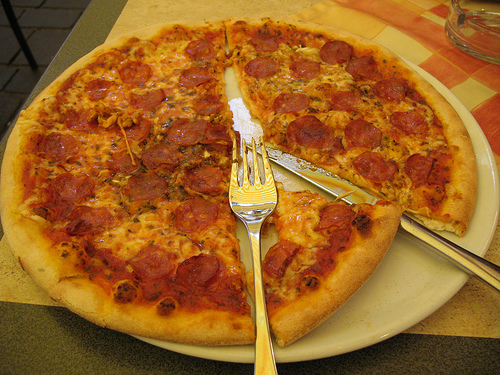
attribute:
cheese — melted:
[111, 187, 208, 271]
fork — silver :
[218, 134, 285, 374]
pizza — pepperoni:
[1, 12, 484, 352]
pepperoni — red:
[108, 147, 179, 205]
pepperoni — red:
[271, 90, 314, 114]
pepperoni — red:
[338, 114, 388, 148]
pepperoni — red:
[317, 40, 353, 64]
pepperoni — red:
[114, 61, 221, 113]